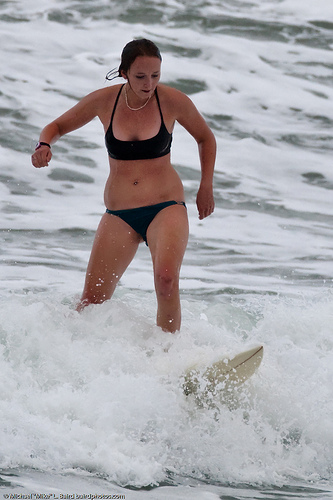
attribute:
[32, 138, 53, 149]
watch — black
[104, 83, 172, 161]
top — black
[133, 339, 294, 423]
surfboard — white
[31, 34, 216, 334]
woman — wearing, riding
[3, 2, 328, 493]
waves — green, white, ocean waves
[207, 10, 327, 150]
ocean waves — white, green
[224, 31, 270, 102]
waves — white, green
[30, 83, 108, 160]
arm — extended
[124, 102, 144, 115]
necklace — white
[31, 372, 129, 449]
wave — crashing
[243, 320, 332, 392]
wave — crashing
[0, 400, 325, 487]
wave — crashing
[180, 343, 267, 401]
board — white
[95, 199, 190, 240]
bikini — bottom